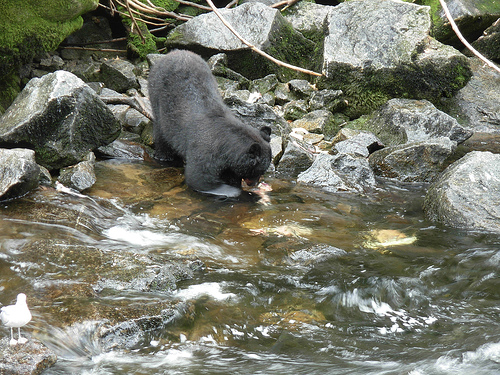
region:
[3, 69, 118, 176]
this is a rock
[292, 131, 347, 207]
this is a rock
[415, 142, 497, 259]
this is a rock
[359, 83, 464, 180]
this is a rock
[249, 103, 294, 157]
this is a rock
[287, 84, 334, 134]
this is a rock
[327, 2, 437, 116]
this is a rock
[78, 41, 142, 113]
this is a rock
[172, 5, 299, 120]
this is a rock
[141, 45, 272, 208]
Black bear catching it's next meal.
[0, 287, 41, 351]
White bird sitting on a rock.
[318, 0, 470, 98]
A gray rock.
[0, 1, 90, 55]
Moss growing on a rock.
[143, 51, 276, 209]
Black bear in water.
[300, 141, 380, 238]
A gray rock in a stream.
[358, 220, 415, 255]
Rock under rushing water.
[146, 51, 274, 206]
Bear getting his paws wet.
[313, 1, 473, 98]
A gray bolder.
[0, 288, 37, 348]
A bird by water.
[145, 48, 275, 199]
Big black bear is wet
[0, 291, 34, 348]
White bird standing on rock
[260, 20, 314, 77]
Green moss on large rock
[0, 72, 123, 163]
Large gray rock next to black bear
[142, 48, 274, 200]
Big black bear is trying to catch food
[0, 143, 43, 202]
Gray rock is wet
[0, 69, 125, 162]
Gray rock is wet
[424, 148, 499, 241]
Gray rock is wet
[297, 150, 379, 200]
Gray rock is wet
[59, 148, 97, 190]
Gray rock is wet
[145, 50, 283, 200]
bear at edge of river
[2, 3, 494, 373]
riverbank with large rocks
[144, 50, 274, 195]
black bear fishing in river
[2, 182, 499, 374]
river rapids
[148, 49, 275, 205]
black bear catching a salmon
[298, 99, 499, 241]
rocks eroded by water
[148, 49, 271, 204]
black bear with salmon in mouth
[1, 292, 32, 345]
seagull standing on rock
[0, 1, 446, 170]
riverbank with large rocks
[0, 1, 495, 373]
seagull waiting for fish scraps after black bear eats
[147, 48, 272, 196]
Bear fishing in a stream.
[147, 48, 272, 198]
Black bear looking for food.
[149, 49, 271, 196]
Black bear standing in the water.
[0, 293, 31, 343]
White bird on a rock.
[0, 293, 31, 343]
White bird watching the bear.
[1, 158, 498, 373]
The stream is moving swiftly.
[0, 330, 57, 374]
Rock that the bird is sitting on.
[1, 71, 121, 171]
Large stone to the left of the bear.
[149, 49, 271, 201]
Bear is trying to catch fish in the stream.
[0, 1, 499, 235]
Large boulders on the shore of the creek.